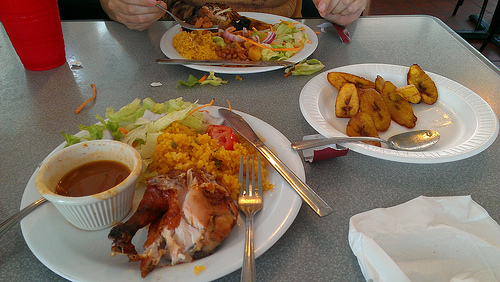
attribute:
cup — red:
[1, 0, 77, 80]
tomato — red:
[207, 123, 237, 146]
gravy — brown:
[53, 158, 130, 195]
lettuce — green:
[105, 96, 193, 124]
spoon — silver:
[275, 119, 459, 167]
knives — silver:
[155, 56, 335, 218]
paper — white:
[288, 117, 365, 184]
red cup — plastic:
[0, 0, 71, 75]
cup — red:
[1, 7, 71, 67]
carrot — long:
[72, 77, 100, 117]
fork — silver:
[159, 7, 208, 38]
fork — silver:
[152, 4, 219, 33]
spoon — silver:
[289, 127, 447, 155]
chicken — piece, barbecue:
[114, 172, 239, 264]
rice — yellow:
[147, 121, 272, 191]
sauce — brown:
[59, 139, 141, 210]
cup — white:
[21, 133, 149, 236]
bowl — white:
[41, 127, 144, 237]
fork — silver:
[151, 6, 225, 35]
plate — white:
[286, 46, 485, 163]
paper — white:
[336, 191, 497, 281]